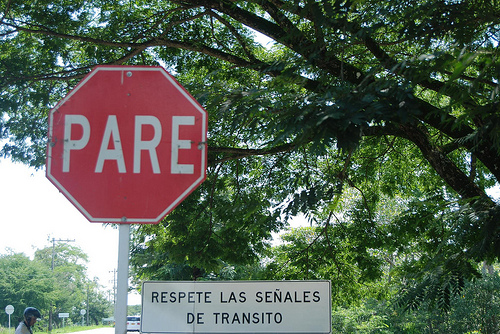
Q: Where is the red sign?
A: Attached to the pole.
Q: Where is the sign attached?
A: Attached to white pole.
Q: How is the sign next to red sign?
A: It is white in color.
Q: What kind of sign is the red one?
A: Stop sign.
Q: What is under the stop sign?
A: Another sign.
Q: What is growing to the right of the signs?
A: Trees.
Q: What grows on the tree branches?
A: Leaves.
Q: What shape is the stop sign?
A: Octagon.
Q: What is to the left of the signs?
A: A road.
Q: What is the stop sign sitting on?
A: Pole.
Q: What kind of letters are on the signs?
A: Capital letters.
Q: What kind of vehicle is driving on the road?
A: Car.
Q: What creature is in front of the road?
A: A man.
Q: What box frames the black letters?
A: The yellow box.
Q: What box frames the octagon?
A: The yellow box.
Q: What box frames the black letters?
A: The yellow box.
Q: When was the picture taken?
A: Daytime.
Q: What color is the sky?
A: White.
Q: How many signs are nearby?
A: Two.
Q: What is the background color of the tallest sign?
A: Red.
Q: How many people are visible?
A: One.